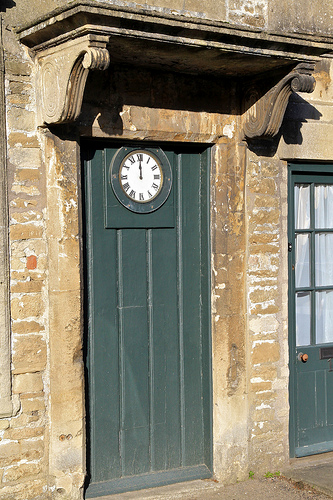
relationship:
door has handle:
[289, 167, 331, 461] [299, 350, 309, 368]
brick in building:
[8, 224, 49, 245] [0, 0, 332, 497]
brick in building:
[13, 293, 44, 319] [0, 0, 332, 497]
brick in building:
[7, 130, 42, 150] [0, 0, 332, 497]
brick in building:
[253, 210, 283, 228] [0, 0, 332, 497]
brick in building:
[250, 232, 282, 245] [0, 0, 332, 497]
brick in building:
[248, 341, 289, 362] [0, 0, 332, 497]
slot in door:
[319, 350, 331, 360] [289, 167, 331, 461]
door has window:
[289, 167, 331, 461] [293, 182, 331, 348]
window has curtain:
[293, 182, 331, 348] [293, 184, 331, 346]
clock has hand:
[115, 150, 168, 203] [139, 158, 143, 181]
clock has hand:
[115, 150, 168, 203] [135, 161, 143, 180]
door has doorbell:
[289, 167, 331, 461] [287, 243, 292, 253]